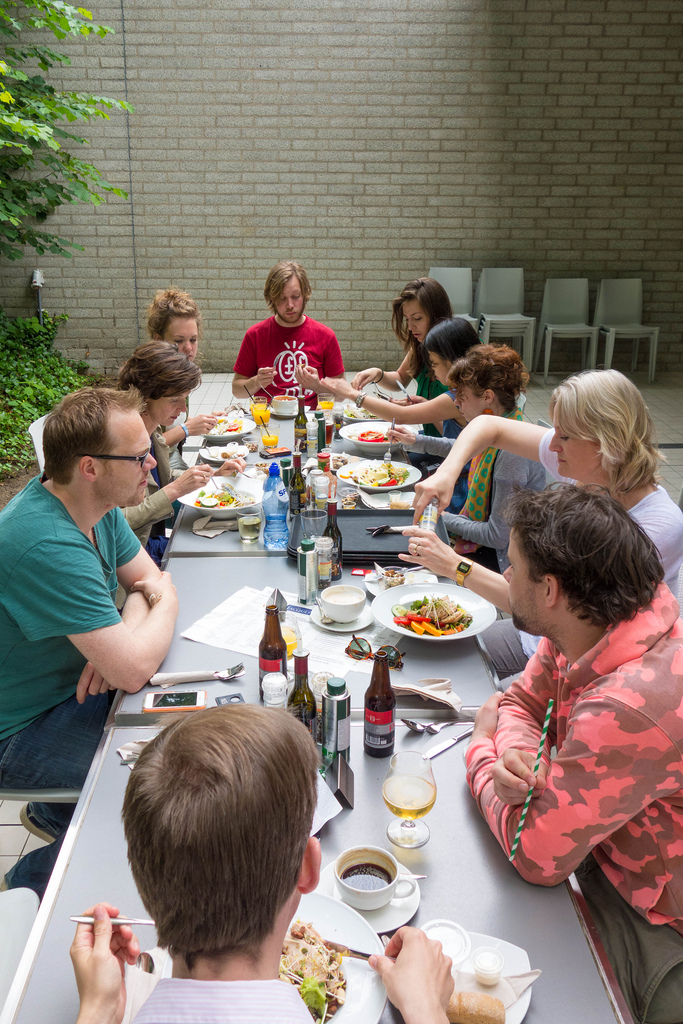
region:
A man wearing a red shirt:
[232, 258, 336, 417]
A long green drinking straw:
[506, 697, 552, 890]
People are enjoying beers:
[366, 643, 441, 859]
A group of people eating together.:
[56, 234, 645, 716]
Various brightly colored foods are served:
[380, 578, 478, 646]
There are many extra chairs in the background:
[394, 234, 675, 379]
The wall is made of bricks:
[193, 30, 604, 255]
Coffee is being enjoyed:
[320, 837, 426, 941]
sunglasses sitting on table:
[343, 632, 412, 678]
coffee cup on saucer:
[327, 840, 416, 911]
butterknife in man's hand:
[307, 933, 382, 972]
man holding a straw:
[509, 680, 567, 871]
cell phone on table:
[142, 684, 208, 716]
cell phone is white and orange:
[132, 681, 209, 715]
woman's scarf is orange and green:
[439, 393, 532, 562]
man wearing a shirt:
[227, 307, 354, 412]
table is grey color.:
[206, 499, 461, 940]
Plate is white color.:
[379, 566, 491, 648]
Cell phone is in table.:
[135, 675, 235, 725]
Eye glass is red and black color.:
[337, 622, 408, 675]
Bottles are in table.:
[238, 597, 404, 761]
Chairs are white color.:
[438, 255, 660, 376]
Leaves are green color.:
[5, 24, 95, 247]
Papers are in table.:
[222, 584, 335, 672]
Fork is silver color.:
[166, 651, 249, 692]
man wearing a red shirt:
[226, 237, 359, 420]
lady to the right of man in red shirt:
[139, 259, 208, 378]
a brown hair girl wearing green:
[351, 273, 451, 404]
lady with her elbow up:
[415, 374, 654, 519]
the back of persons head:
[117, 663, 345, 977]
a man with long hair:
[482, 482, 681, 666]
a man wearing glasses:
[3, 390, 206, 779]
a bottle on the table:
[280, 456, 327, 517]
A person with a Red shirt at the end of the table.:
[225, 256, 354, 419]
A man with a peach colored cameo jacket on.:
[465, 483, 681, 926]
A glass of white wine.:
[379, 743, 446, 855]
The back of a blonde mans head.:
[108, 697, 345, 993]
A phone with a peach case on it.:
[127, 680, 217, 720]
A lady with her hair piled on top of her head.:
[126, 284, 212, 381]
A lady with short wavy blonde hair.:
[538, 358, 676, 529]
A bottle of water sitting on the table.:
[255, 457, 296, 561]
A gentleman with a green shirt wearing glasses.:
[4, 381, 183, 803]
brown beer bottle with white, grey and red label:
[361, 648, 401, 761]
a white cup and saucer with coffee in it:
[322, 840, 426, 939]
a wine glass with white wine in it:
[375, 748, 443, 853]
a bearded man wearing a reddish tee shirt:
[233, 257, 349, 424]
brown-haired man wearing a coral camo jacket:
[463, 476, 681, 961]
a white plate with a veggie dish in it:
[379, 576, 499, 649]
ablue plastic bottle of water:
[256, 462, 294, 556]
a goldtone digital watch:
[450, 554, 475, 589]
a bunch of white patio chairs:
[422, 261, 663, 391]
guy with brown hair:
[63, 701, 453, 1022]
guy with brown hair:
[52, 691, 466, 1022]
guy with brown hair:
[60, 683, 468, 1015]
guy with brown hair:
[66, 694, 479, 1021]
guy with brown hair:
[65, 698, 469, 1020]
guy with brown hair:
[56, 688, 469, 1015]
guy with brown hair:
[60, 684, 473, 1019]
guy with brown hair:
[68, 696, 477, 1015]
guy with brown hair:
[63, 699, 480, 1018]